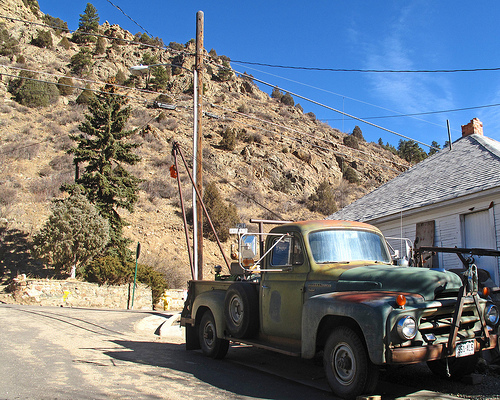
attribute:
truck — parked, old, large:
[180, 218, 499, 399]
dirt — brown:
[0, 303, 364, 399]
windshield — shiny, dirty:
[307, 229, 391, 264]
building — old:
[323, 118, 500, 289]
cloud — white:
[347, 1, 500, 136]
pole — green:
[197, 10, 205, 279]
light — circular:
[398, 316, 417, 340]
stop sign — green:
[130, 242, 141, 309]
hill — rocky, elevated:
[0, 1, 425, 305]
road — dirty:
[0, 303, 397, 400]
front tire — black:
[322, 326, 379, 398]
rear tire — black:
[198, 309, 229, 359]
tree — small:
[36, 191, 111, 281]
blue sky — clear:
[35, 1, 500, 154]